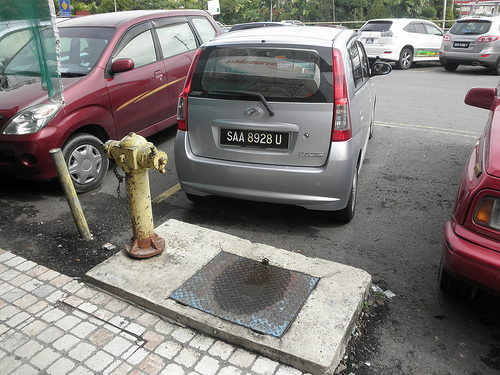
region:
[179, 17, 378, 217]
a parked silver minivan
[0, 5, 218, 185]
a maroon red minivan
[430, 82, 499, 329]
a parked red car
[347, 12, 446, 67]
a parked white car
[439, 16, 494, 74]
a parked silver car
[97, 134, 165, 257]
a yellow fire hydrant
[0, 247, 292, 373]
a stone paved sidewalk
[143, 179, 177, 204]
a yellow parking line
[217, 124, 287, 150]
a car license plate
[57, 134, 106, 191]
a car's front tire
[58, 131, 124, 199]
a black tire with a silver hubcap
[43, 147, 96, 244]
a yellow metal pole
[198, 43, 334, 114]
a back windshield with a wiper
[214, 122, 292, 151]
a black license plate with white lettering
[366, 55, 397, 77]
a black side mirror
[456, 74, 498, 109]
a red side mirror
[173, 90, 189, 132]
a group of tail lights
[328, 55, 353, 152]
a group of tail lights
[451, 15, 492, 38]
a rear window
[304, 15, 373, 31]
part of a fence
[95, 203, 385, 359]
A thick concrete square area.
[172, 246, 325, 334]
A square metal cover.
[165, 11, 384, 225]
A silver four door vehicle.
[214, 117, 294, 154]
Black license tag on back of vehicle.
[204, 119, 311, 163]
Black license tag with white letters and numbers..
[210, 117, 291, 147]
SAA 8928 U on license tag.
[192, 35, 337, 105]
Back windshield of silver vehicle.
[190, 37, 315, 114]
Windshield wiper on back of silver vehicle.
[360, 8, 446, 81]
White vehicle with green design.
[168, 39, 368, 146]
Taillights on back of silver vehicle.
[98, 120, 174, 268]
Rusty old city fire hydrant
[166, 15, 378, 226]
Car not parked properly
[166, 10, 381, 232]
Car back into a parking spot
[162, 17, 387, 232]
Car in a store parking lot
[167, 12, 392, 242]
Car parked close by an office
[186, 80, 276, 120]
Windshield wiper of a car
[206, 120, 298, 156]
Back license plate of a car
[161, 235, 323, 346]
Square metal plate covering a hole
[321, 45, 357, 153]
Taillights on back of a car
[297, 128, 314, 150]
Trunk keyhole for a car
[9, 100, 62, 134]
the headlight of a car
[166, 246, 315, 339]
a metal cover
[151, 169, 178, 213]
a yellow parking line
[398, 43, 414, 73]
a black tire with silver hubcap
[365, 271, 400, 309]
some trash in the parking lot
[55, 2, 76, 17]
a blue and yellow sign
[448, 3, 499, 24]
part of a white building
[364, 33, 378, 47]
a vehicle's license plate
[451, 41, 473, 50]
a vehicle's license plate